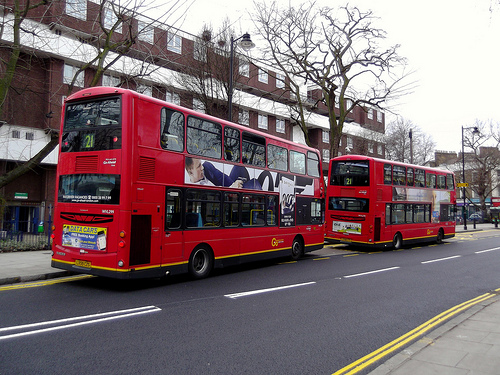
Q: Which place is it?
A: It is a street.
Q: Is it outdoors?
A: Yes, it is outdoors.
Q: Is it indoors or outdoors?
A: It is outdoors.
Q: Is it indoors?
A: No, it is outdoors.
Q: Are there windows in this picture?
A: Yes, there is a window.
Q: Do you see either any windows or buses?
A: Yes, there is a window.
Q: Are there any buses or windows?
A: Yes, there is a window.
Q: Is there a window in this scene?
A: Yes, there is a window.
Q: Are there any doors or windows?
A: Yes, there is a window.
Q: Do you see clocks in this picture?
A: No, there are no clocks.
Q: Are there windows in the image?
A: Yes, there is a window.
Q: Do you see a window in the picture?
A: Yes, there is a window.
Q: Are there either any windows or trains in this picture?
A: Yes, there is a window.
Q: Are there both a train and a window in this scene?
A: No, there is a window but no trains.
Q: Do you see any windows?
A: Yes, there is a window.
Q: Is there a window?
A: Yes, there is a window.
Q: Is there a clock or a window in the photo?
A: Yes, there is a window.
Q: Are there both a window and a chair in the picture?
A: No, there is a window but no chairs.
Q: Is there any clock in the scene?
A: No, there are no clocks.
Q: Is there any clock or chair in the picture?
A: No, there are no clocks or chairs.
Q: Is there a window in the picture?
A: Yes, there are windows.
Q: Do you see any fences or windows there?
A: Yes, there are windows.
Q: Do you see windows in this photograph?
A: Yes, there is a window.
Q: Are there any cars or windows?
A: Yes, there is a window.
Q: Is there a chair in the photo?
A: No, there are no chairs.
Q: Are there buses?
A: Yes, there is a bus.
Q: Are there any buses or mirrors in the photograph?
A: Yes, there is a bus.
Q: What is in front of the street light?
A: The bus is in front of the street light.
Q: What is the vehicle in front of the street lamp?
A: The vehicle is a bus.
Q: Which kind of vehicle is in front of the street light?
A: The vehicle is a bus.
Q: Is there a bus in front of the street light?
A: Yes, there is a bus in front of the street light.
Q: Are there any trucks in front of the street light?
A: No, there is a bus in front of the street light.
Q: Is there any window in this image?
A: Yes, there is a window.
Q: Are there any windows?
A: Yes, there is a window.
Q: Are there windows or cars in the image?
A: Yes, there is a window.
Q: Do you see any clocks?
A: No, there are no clocks.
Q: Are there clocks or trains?
A: No, there are no clocks or trains.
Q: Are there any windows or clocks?
A: Yes, there is a window.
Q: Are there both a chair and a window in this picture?
A: No, there is a window but no chairs.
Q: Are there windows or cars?
A: Yes, there is a window.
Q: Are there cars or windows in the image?
A: Yes, there is a window.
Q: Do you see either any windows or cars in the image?
A: Yes, there is a window.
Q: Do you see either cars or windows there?
A: Yes, there is a window.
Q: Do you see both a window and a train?
A: No, there is a window but no trains.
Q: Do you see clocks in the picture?
A: No, there are no clocks.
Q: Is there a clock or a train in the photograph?
A: No, there are no clocks or trains.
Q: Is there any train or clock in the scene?
A: No, there are no clocks or trains.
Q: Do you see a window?
A: Yes, there is a window.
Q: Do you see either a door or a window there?
A: Yes, there is a window.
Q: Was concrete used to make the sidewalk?
A: Yes, the sidewalk is made of concrete.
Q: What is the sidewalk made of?
A: The sidewalk is made of cement.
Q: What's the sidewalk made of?
A: The sidewalk is made of concrete.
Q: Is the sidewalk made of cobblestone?
A: No, the sidewalk is made of cement.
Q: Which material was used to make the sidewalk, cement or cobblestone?
A: The sidewalk is made of cement.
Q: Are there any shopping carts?
A: No, there are no shopping carts.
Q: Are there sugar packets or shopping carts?
A: No, there are no shopping carts or sugar packets.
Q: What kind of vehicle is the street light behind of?
A: The street light is behind the bus.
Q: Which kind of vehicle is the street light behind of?
A: The street light is behind the bus.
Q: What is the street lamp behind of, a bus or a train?
A: The street lamp is behind a bus.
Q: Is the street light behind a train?
A: No, the street light is behind the bus.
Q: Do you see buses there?
A: Yes, there is a bus.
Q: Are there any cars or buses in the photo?
A: Yes, there is a bus.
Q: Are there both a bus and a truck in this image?
A: No, there is a bus but no trucks.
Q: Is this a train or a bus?
A: This is a bus.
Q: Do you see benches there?
A: No, there are no benches.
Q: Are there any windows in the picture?
A: Yes, there is a window.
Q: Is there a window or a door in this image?
A: Yes, there is a window.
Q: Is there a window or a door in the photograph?
A: Yes, there is a window.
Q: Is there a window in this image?
A: Yes, there is a window.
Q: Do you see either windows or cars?
A: Yes, there is a window.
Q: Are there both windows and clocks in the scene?
A: No, there is a window but no clocks.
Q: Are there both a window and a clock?
A: No, there is a window but no clocks.